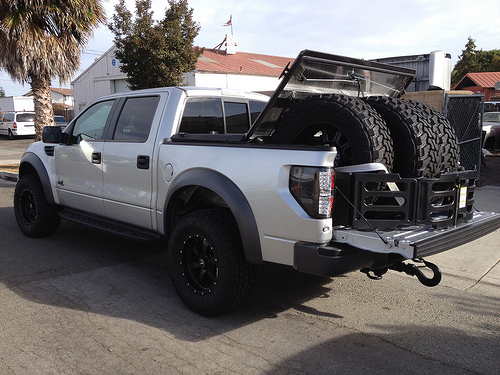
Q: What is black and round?
A: Tires.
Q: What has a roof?
A: The houses.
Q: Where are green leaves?
A: The trees.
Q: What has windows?
A: The vehicle.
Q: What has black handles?
A: The truck doors.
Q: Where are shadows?
A: On the pavement.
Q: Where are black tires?
A: On back of truck.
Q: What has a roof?
A: The houses.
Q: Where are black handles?
A: On truck doors.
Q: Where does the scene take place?
A: On a residential street.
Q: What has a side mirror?
A: The truck.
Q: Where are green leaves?
A: On trees.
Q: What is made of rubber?
A: The tires.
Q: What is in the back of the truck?
A: Tires.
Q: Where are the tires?
A: In the truck.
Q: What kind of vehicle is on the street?
A: Truck.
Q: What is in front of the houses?
A: Trees.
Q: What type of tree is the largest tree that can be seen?
A: A palm tree.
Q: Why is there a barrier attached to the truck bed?
A: To prevent the wheels from falling off the truck.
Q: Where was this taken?
A: In a parking lot.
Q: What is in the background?
A: Buildings.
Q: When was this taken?
A: During the day.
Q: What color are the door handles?
A: Black.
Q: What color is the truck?
A: Silver.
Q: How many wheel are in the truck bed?
A: Four.